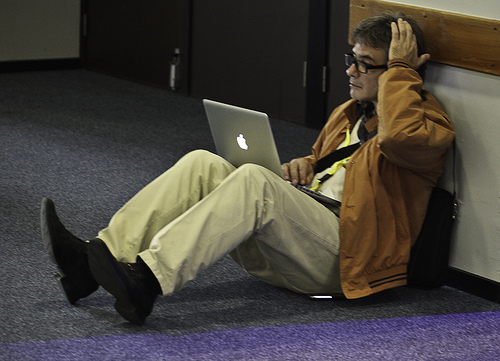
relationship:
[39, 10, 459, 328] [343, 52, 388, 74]
man with glasses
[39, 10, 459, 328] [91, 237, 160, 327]
man has shoe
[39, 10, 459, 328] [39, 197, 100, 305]
man has shoe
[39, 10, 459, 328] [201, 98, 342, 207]
man with laptop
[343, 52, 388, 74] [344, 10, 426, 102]
glasses on head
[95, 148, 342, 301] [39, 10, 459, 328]
pants on man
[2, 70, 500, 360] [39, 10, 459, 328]
carpet under man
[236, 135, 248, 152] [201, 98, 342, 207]
apple on laptop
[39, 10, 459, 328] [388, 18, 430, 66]
man has hand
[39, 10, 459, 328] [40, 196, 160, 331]
man with shoes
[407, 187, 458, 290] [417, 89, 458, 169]
bag on shoulders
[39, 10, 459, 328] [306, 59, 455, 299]
man in jacket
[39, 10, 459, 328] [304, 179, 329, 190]
man with idcard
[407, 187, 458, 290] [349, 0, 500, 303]
bag on wall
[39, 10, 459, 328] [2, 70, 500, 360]
man on carpet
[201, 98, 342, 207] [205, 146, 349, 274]
laptop on lap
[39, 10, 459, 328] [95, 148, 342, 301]
man in pants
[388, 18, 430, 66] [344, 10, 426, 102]
hand on head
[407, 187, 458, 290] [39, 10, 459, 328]
bag near man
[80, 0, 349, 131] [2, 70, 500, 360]
doorway near carpet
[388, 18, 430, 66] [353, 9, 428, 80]
hand on hair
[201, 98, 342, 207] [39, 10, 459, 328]
laptop on man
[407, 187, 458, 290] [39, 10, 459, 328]
bag behind man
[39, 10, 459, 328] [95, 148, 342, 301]
man with pants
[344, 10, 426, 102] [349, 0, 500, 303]
head on wall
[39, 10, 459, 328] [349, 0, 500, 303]
man against wall